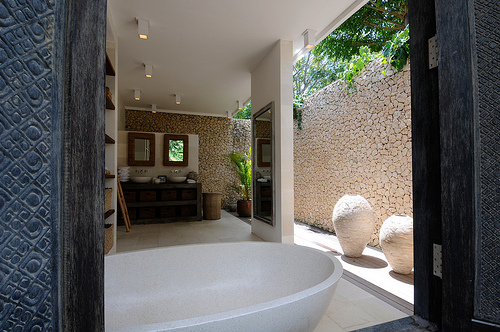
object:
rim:
[104, 238, 349, 331]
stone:
[392, 140, 404, 149]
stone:
[404, 140, 412, 150]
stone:
[371, 148, 379, 157]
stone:
[392, 99, 400, 109]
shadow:
[339, 252, 388, 269]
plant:
[229, 98, 254, 121]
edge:
[294, 51, 383, 102]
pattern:
[0, 0, 66, 331]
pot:
[329, 192, 376, 259]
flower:
[168, 139, 184, 162]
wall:
[294, 24, 417, 252]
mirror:
[133, 138, 151, 162]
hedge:
[228, 99, 255, 120]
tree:
[292, 0, 413, 100]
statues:
[374, 212, 413, 277]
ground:
[105, 208, 437, 330]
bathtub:
[104, 238, 348, 331]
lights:
[137, 33, 150, 40]